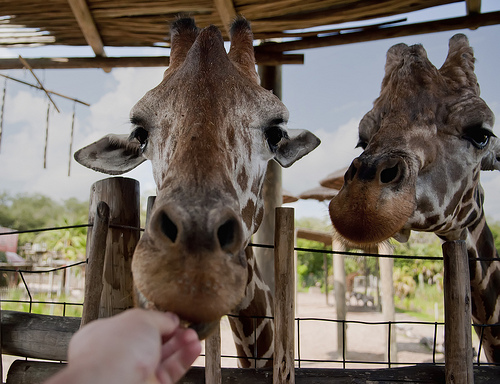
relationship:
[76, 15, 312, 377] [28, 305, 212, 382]
giraffe taking hand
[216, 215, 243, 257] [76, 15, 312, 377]
nostril of giraffe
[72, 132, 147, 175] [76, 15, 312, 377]
ear of giraffe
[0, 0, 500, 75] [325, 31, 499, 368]
roof of giraffe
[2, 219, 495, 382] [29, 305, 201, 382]
fence dividing person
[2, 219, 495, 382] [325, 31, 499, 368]
fence dividing giraffe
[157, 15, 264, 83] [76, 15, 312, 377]
horns on giraffe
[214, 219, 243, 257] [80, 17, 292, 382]
nostrils of giraffe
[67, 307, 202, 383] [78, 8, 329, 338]
hand petting giraffe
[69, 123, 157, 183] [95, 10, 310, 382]
ear of giraffe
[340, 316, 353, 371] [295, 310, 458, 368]
wire on fence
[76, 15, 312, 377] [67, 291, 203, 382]
giraffe eating from hand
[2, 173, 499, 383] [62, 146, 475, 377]
fence with posts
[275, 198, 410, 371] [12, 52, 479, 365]
structure in area